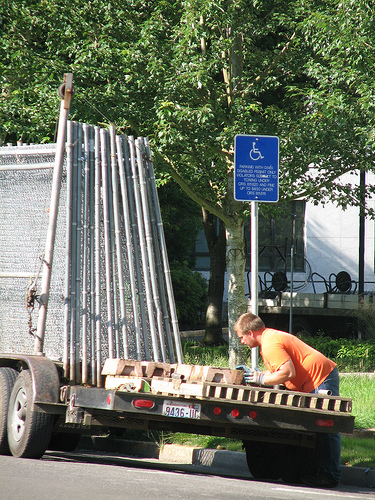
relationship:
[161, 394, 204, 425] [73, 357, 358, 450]
plate on trailer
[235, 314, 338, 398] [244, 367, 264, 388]
man wearing gloves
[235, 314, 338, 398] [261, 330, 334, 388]
man with shirt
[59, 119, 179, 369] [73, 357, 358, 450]
fence on trailer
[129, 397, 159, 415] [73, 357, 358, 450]
lights on trailer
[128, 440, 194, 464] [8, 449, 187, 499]
curb on street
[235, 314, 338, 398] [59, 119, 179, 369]
man loading fence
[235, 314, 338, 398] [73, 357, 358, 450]
man with trailer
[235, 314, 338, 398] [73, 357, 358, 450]
man loading trailer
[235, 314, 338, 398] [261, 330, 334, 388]
man wearing shirt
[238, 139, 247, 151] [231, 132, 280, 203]
blue handicapped sign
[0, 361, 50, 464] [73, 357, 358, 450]
tires to trailer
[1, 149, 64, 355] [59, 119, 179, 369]
sections of fence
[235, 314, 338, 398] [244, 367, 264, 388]
man with gloves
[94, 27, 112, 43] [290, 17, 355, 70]
healthy green leaves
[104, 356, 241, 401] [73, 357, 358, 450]
pallets on trailer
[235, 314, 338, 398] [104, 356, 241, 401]
man near pallets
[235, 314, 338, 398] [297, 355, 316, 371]
man wearing orange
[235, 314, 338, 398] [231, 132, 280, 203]
man next sign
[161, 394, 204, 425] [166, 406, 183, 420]
plate has numbers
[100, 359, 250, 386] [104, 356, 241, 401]
cinder blocks on pallets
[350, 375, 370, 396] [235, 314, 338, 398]
grass behind man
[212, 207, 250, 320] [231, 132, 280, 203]
tree near sign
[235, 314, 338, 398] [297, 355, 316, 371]
man in orange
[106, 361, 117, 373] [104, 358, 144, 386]
red colored bricks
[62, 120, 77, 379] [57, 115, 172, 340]
rows of poles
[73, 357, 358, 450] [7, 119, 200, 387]
trailer with supplies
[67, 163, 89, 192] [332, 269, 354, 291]
metal lawn chairs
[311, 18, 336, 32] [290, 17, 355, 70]
green tree leaves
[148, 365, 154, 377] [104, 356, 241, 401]
yellow wooden pallets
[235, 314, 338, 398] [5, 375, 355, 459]
man over truck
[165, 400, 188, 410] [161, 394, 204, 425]
louisiana license plate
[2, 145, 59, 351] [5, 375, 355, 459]
fencing on truck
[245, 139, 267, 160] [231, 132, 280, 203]
handicapped parking sign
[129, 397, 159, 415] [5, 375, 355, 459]
lights on truck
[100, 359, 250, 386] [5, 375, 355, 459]
cinder blocks on truck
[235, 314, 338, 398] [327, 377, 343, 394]
man wearing jeans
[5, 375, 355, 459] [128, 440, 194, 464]
truck parked curb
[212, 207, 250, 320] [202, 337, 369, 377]
tree in yard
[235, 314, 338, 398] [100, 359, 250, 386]
man leaning on top of cinder blocks